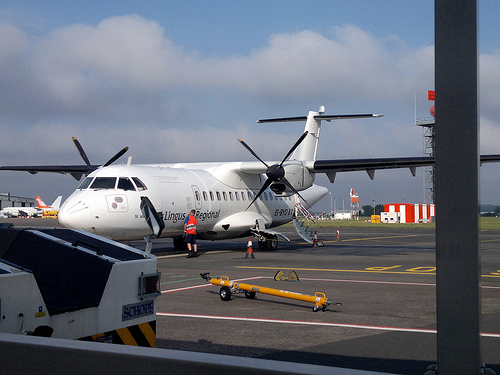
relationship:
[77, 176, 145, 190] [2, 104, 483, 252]
window on airplane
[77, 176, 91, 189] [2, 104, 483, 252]
window on airplane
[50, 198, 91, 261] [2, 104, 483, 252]
nose on an airplane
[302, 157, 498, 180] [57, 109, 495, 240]
wing on an airplane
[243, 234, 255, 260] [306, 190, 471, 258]
cone on airfield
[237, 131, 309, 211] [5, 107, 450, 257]
propeller on airplane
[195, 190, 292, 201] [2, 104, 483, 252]
porthole windows on airplane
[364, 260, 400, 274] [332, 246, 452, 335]
p on tarmac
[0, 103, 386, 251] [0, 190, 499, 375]
aircraft on airfield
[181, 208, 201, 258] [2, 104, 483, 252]
man next to airplane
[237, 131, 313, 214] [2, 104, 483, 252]
propeller on airplane